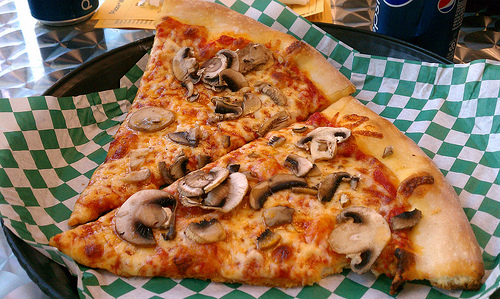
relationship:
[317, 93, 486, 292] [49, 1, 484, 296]
crust on pizza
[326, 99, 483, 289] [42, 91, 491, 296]
crust on pizza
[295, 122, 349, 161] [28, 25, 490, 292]
mushroom on pizza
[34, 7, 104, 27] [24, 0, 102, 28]
bottom on bottom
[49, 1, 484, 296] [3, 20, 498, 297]
pizza on paper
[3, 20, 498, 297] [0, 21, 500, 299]
paper on black plate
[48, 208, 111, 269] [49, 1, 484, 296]
tips on pizza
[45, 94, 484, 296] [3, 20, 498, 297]
pizza on paper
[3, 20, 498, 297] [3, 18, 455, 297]
paper on black plate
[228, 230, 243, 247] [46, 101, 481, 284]
cheese on pizza slice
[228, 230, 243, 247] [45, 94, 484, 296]
cheese on pizza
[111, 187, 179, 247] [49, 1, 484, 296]
mushroom on pizza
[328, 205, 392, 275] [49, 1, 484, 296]
mushroom on pizza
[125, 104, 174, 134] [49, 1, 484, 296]
mushroom on pizza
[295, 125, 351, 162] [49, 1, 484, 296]
mushroom on pizza